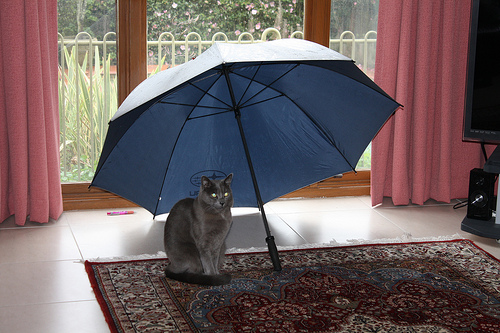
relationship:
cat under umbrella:
[163, 174, 233, 286] [87, 38, 403, 272]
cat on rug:
[163, 174, 233, 286] [85, 234, 499, 332]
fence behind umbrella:
[56, 28, 378, 82] [87, 38, 403, 272]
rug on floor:
[85, 234, 499, 332] [0, 197, 499, 332]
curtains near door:
[1, 0, 65, 224] [119, 0, 330, 104]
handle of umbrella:
[264, 235, 283, 271] [87, 38, 403, 272]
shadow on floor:
[129, 212, 287, 254] [0, 197, 499, 332]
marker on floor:
[107, 210, 137, 215] [0, 197, 499, 332]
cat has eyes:
[163, 174, 233, 286] [211, 191, 229, 198]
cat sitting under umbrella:
[163, 174, 233, 286] [87, 38, 403, 272]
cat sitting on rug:
[163, 174, 233, 286] [85, 234, 499, 332]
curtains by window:
[1, 0, 65, 224] [56, 0, 118, 185]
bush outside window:
[59, 1, 305, 61] [145, 0, 304, 74]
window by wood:
[56, 0, 118, 185] [119, 0, 147, 107]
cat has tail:
[163, 174, 233, 286] [163, 265, 231, 286]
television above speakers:
[461, 0, 499, 144] [466, 166, 495, 220]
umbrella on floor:
[87, 38, 403, 272] [0, 197, 499, 332]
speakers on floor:
[466, 166, 495, 220] [0, 197, 499, 332]